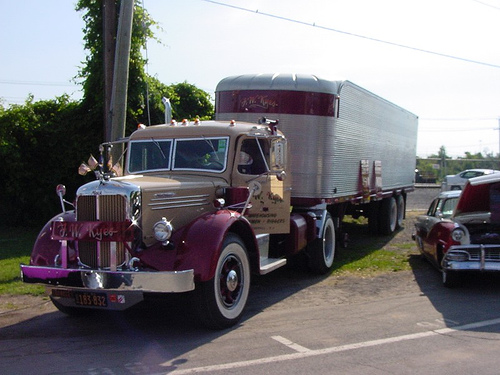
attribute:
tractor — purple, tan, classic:
[17, 95, 339, 333]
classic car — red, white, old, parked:
[412, 170, 500, 290]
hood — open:
[450, 168, 499, 222]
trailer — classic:
[213, 71, 421, 277]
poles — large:
[99, 0, 137, 180]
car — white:
[444, 167, 500, 194]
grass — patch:
[1, 225, 418, 300]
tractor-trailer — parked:
[19, 68, 421, 332]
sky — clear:
[2, 0, 500, 160]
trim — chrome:
[126, 136, 233, 177]